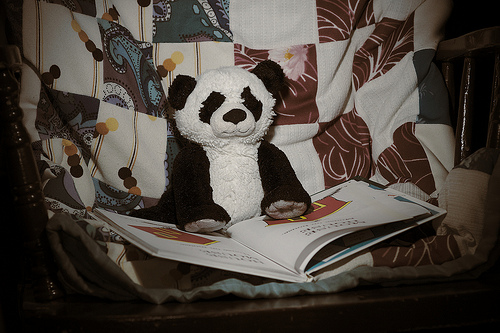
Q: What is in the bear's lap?
A: A book.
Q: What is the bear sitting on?
A: A chair.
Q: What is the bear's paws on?
A: Book pages.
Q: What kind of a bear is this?
A: A panda bear.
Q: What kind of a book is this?
A: A children's book.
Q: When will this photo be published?
A: Next week.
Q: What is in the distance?
A: A chair.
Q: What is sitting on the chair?
A: Bear.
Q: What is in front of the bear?
A: Book.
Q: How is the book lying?
A: Open.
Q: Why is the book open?
A: Bear reading.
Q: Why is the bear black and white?
A: Panda.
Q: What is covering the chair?
A: Blanket.